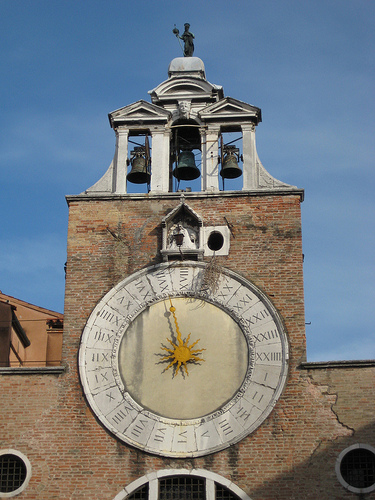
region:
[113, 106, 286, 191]
Three bells on top of the building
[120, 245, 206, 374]
Yellow hand on the Sundial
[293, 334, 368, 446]
Crack in the building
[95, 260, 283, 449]
Roman numerals around the Sundial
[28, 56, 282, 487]
Ancient monument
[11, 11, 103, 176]
Blue sky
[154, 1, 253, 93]
Statue on the top of the building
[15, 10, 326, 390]
Bright sunny day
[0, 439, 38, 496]
Round opening in the building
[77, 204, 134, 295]
Old brick building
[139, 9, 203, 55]
Statue on the top of the building.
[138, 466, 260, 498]
Window on the building.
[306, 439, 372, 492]
Round window on the building.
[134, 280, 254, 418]
Hands on the clock.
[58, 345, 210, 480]
Numbers on the clock.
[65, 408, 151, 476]
Brick on the building.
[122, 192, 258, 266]
Design on the building.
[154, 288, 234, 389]
Sun shaped hand on the clock.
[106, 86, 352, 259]
Bells on the tower.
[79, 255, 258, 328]
Roman numerals on the clock.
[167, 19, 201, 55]
the statue on the rop of the building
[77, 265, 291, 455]
an oversized clock on the building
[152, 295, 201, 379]
the hand on the clock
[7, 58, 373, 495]
a large brick building with bells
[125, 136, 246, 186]
the bells on the top of the clock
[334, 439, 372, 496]
the window of the building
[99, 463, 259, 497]
the window of the building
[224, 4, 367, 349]
a big chunk of blue sky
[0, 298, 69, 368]
another building in the back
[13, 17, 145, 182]
more of the blue sky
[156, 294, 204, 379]
a yellow sun and clock hand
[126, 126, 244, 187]
3 bells at the top of the tower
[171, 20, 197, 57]
a statue at the top of the tower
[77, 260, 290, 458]
a white clock with Roman numerals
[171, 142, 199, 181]
a green bell in the middle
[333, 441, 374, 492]
a small round window on the bottom right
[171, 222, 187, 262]
a lantern on top of the clock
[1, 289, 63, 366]
a tan building in the background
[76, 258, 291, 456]
a large white sundial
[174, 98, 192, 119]
a face above the middle bell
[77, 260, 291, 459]
large clock on tower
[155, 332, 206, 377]
center of hand resembles sun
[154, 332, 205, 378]
center of hand is yellow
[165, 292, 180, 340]
hour hand is yellow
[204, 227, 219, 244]
oval hole above clock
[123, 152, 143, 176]
old bell is left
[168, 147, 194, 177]
old bell is middle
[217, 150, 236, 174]
old bell is right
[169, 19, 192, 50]
statue on top of tower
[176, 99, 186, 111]
face sculpture above middle bell